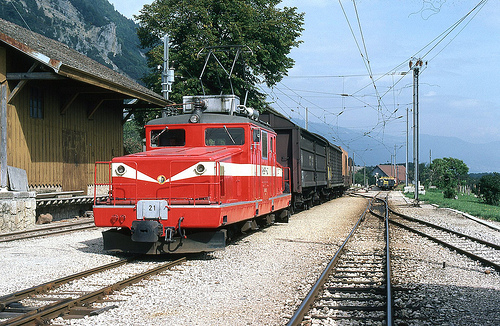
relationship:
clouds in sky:
[251, 37, 498, 123] [312, 0, 496, 155]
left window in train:
[197, 118, 259, 153] [88, 70, 380, 267]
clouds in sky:
[251, 37, 498, 123] [290, 59, 492, 148]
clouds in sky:
[251, 37, 498, 123] [113, 2, 498, 152]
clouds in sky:
[251, 37, 498, 123] [296, 0, 493, 110]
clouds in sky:
[251, 37, 498, 123] [116, 0, 494, 190]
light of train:
[192, 161, 208, 175] [91, 87, 356, 246]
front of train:
[88, 100, 294, 251] [91, 87, 356, 246]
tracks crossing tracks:
[420, 216, 483, 261] [311, 261, 406, 321]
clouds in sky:
[251, 37, 498, 123] [311, 11, 482, 139]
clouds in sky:
[251, 37, 498, 123] [242, 0, 496, 124]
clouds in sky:
[251, 37, 498, 123] [375, 9, 424, 52]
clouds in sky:
[251, 37, 498, 123] [108, 0, 497, 172]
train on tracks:
[87, 85, 359, 260] [1, 251, 233, 323]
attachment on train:
[128, 217, 160, 245] [92, 107, 229, 255]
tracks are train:
[346, 189, 498, 271] [110, 89, 362, 245]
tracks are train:
[284, 188, 391, 322] [110, 89, 362, 245]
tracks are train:
[1, 255, 183, 324] [110, 89, 362, 245]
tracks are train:
[1, 217, 96, 244] [110, 89, 362, 245]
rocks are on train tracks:
[148, 277, 192, 305] [58, 262, 135, 316]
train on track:
[92, 94, 356, 253] [7, 248, 188, 320]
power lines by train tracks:
[277, 2, 470, 122] [297, 190, 498, 322]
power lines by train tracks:
[277, 2, 470, 122] [12, 235, 185, 323]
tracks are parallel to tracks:
[278, 186, 420, 324] [2, 173, 497, 323]